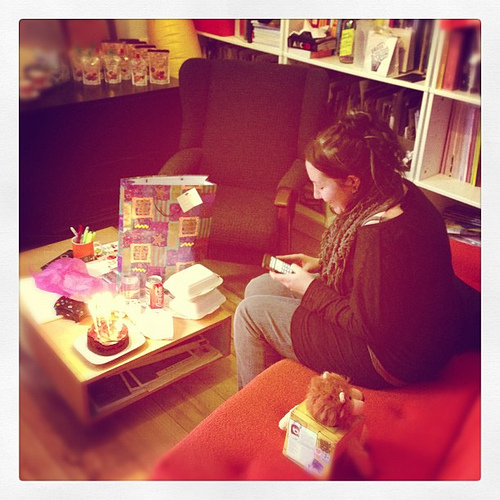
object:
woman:
[232, 107, 456, 391]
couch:
[144, 234, 481, 480]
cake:
[87, 319, 129, 355]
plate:
[72, 317, 147, 366]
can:
[144, 274, 164, 311]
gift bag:
[115, 174, 217, 299]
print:
[132, 194, 205, 260]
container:
[162, 263, 224, 302]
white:
[190, 271, 195, 281]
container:
[167, 288, 226, 321]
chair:
[155, 57, 331, 269]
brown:
[251, 107, 278, 147]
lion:
[306, 370, 367, 430]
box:
[280, 399, 365, 480]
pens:
[76, 223, 84, 244]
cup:
[70, 233, 95, 258]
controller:
[53, 296, 89, 323]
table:
[19, 225, 232, 428]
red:
[409, 408, 451, 459]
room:
[18, 18, 482, 480]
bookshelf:
[192, 18, 481, 250]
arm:
[273, 157, 308, 255]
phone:
[261, 253, 296, 275]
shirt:
[289, 176, 454, 390]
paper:
[34, 257, 104, 301]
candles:
[87, 291, 126, 337]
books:
[438, 100, 456, 175]